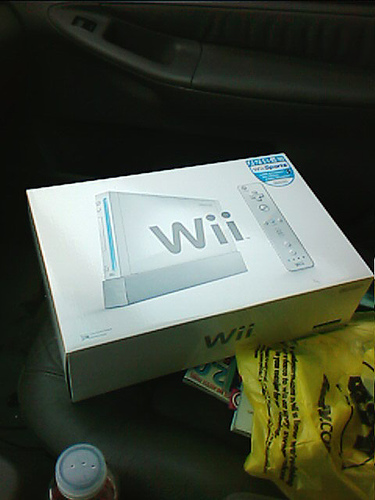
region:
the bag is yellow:
[240, 354, 370, 483]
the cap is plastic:
[57, 441, 109, 494]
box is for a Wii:
[30, 178, 354, 362]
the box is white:
[15, 167, 362, 367]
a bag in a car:
[208, 312, 364, 470]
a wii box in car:
[46, 188, 299, 400]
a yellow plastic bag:
[230, 330, 371, 485]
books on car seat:
[145, 329, 367, 489]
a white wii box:
[88, 183, 307, 346]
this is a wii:
[38, 142, 344, 394]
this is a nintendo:
[97, 150, 297, 352]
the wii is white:
[105, 202, 213, 270]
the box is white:
[78, 234, 251, 410]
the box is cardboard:
[18, 226, 249, 349]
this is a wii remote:
[204, 177, 345, 279]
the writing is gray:
[124, 198, 256, 263]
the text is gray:
[151, 201, 258, 253]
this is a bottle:
[47, 428, 125, 481]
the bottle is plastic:
[36, 444, 131, 491]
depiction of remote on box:
[235, 179, 312, 273]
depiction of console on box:
[97, 187, 247, 293]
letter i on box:
[209, 210, 228, 244]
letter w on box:
[138, 209, 206, 247]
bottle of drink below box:
[32, 428, 118, 496]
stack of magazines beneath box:
[194, 355, 269, 441]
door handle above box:
[54, 10, 199, 85]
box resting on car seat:
[23, 151, 361, 370]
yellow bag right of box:
[243, 347, 373, 494]